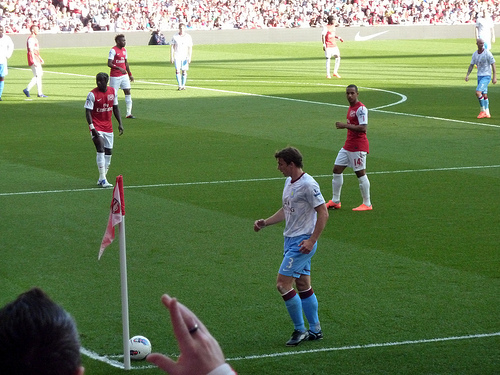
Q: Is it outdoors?
A: Yes, it is outdoors.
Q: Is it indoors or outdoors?
A: It is outdoors.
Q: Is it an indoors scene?
A: No, it is outdoors.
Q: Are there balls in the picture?
A: Yes, there is a ball.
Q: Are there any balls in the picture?
A: Yes, there is a ball.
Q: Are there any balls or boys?
A: Yes, there is a ball.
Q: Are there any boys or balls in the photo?
A: Yes, there is a ball.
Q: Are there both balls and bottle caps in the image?
A: No, there is a ball but no bottle caps.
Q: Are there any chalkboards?
A: No, there are no chalkboards.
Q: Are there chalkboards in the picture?
A: No, there are no chalkboards.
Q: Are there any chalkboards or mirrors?
A: No, there are no chalkboards or mirrors.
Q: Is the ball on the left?
A: Yes, the ball is on the left of the image.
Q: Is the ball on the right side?
A: No, the ball is on the left of the image.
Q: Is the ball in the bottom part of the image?
A: Yes, the ball is in the bottom of the image.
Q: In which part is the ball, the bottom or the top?
A: The ball is in the bottom of the image.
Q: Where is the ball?
A: The ball is on the field.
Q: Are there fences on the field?
A: No, there is a ball on the field.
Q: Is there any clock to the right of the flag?
A: No, there is a ball to the right of the flag.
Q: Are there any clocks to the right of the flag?
A: No, there is a ball to the right of the flag.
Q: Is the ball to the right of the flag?
A: Yes, the ball is to the right of the flag.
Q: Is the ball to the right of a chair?
A: No, the ball is to the right of the flag.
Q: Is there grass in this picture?
A: Yes, there is grass.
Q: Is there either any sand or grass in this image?
A: Yes, there is grass.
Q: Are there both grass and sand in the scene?
A: No, there is grass but no sand.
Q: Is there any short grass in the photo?
A: Yes, there is short grass.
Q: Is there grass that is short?
A: Yes, there is grass that is short.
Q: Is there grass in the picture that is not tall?
A: Yes, there is short grass.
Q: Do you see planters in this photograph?
A: No, there are no planters.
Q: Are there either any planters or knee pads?
A: No, there are no planters or knee pads.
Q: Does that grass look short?
A: Yes, the grass is short.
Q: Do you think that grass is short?
A: Yes, the grass is short.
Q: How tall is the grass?
A: The grass is short.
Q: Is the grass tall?
A: No, the grass is short.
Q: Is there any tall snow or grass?
A: No, there is grass but it is short.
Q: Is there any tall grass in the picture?
A: No, there is grass but it is short.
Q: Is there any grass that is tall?
A: No, there is grass but it is short.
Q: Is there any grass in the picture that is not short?
A: No, there is grass but it is short.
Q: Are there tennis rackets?
A: No, there are no tennis rackets.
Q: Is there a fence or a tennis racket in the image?
A: No, there are no rackets or fences.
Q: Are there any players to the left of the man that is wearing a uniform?
A: Yes, there is a player to the left of the man.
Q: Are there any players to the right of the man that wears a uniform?
A: No, the player is to the left of the man.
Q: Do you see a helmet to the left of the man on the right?
A: No, there is a player to the left of the man.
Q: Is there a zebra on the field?
A: No, there is a player on the field.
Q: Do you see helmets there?
A: No, there are no helmets.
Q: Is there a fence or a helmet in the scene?
A: No, there are no helmets or fences.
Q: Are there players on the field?
A: Yes, there is a player on the field.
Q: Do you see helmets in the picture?
A: No, there are no helmets.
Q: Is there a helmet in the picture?
A: No, there are no helmets.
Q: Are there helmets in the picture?
A: No, there are no helmets.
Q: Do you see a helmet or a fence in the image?
A: No, there are no helmets or fences.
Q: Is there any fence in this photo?
A: No, there are no fences.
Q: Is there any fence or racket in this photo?
A: No, there are no fences or rackets.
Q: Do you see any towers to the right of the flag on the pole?
A: No, there is a player to the right of the flag.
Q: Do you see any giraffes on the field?
A: No, there is a player on the field.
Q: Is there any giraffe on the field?
A: No, there is a player on the field.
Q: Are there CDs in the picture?
A: No, there are no cds.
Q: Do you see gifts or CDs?
A: No, there are no CDs or gifts.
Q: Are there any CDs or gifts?
A: No, there are no CDs or gifts.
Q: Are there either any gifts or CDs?
A: No, there are no CDs or gifts.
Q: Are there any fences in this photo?
A: No, there are no fences.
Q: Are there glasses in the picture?
A: No, there are no glasses.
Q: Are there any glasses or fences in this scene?
A: No, there are no glasses or fences.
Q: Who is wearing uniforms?
A: The men are wearing uniforms.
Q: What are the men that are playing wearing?
A: The men are wearing uniforms.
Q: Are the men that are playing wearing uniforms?
A: Yes, the men are wearing uniforms.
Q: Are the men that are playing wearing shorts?
A: No, the men are wearing uniforms.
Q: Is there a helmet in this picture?
A: No, there are no helmets.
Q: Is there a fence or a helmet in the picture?
A: No, there are no helmets or fences.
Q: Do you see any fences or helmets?
A: No, there are no helmets or fences.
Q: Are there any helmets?
A: No, there are no helmets.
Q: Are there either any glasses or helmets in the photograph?
A: No, there are no helmets or glasses.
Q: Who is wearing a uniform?
A: The man is wearing a uniform.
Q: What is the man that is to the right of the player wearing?
A: The man is wearing a uniform.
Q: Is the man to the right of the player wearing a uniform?
A: Yes, the man is wearing a uniform.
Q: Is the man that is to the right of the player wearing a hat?
A: No, the man is wearing a uniform.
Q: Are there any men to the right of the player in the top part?
A: Yes, there is a man to the right of the player.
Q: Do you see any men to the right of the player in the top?
A: Yes, there is a man to the right of the player.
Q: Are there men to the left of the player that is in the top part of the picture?
A: No, the man is to the right of the player.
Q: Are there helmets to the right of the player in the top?
A: No, there is a man to the right of the player.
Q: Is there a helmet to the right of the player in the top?
A: No, there is a man to the right of the player.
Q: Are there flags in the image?
A: Yes, there is a flag.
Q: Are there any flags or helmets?
A: Yes, there is a flag.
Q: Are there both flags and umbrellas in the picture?
A: No, there is a flag but no umbrellas.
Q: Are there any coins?
A: No, there are no coins.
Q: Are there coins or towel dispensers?
A: No, there are no coins or towel dispensers.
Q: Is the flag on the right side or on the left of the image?
A: The flag is on the left of the image.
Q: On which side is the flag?
A: The flag is on the left of the image.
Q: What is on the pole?
A: The flag is on the pole.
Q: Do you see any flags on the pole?
A: Yes, there is a flag on the pole.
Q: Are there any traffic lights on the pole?
A: No, there is a flag on the pole.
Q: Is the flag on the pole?
A: Yes, the flag is on the pole.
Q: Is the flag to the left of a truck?
A: No, the flag is to the left of a player.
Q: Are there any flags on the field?
A: Yes, there is a flag on the field.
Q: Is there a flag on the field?
A: Yes, there is a flag on the field.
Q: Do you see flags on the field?
A: Yes, there is a flag on the field.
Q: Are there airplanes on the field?
A: No, there is a flag on the field.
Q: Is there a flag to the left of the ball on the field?
A: Yes, there is a flag to the left of the ball.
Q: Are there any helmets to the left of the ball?
A: No, there is a flag to the left of the ball.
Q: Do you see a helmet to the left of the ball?
A: No, there is a flag to the left of the ball.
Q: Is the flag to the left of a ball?
A: Yes, the flag is to the left of a ball.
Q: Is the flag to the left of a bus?
A: No, the flag is to the left of a ball.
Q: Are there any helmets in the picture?
A: No, there are no helmets.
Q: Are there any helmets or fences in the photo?
A: No, there are no helmets or fences.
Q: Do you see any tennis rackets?
A: No, there are no tennis rackets.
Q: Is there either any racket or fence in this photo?
A: No, there are no rackets or fences.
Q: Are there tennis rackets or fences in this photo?
A: No, there are no tennis rackets or fences.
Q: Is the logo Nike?
A: Yes, the logo is nike.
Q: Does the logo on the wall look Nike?
A: Yes, the logo is nike.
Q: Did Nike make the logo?
A: Yes, the logo was made by nike.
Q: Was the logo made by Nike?
A: Yes, the logo was made by nike.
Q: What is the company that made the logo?
A: The company that made the logo is nike.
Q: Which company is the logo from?
A: The logo is from nike.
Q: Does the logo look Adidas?
A: No, the logo is nike.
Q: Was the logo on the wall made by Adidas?
A: No, the logo was made by nike.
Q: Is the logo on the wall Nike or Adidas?
A: The logo is nike.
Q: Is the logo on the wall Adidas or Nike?
A: The logo is nike.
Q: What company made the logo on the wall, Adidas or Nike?
A: The logo was made nike.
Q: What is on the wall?
A: The logo is on the wall.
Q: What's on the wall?
A: The logo is on the wall.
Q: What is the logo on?
A: The logo is on the wall.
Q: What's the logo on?
A: The logo is on the wall.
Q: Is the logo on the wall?
A: Yes, the logo is on the wall.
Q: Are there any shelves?
A: No, there are no shelves.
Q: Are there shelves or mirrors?
A: No, there are no shelves or mirrors.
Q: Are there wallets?
A: No, there are no wallets.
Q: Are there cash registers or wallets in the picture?
A: No, there are no wallets or cash registers.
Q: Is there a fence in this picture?
A: No, there are no fences.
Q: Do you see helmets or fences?
A: No, there are no fences or helmets.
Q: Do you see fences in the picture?
A: No, there are no fences.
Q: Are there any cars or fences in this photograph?
A: No, there are no fences or cars.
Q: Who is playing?
A: The people are playing.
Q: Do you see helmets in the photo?
A: No, there are no helmets.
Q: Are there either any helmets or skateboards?
A: No, there are no helmets or skateboards.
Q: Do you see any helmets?
A: No, there are no helmets.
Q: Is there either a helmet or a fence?
A: No, there are no helmets or fences.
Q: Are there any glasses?
A: No, there are no glasses.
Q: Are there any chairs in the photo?
A: No, there are no chairs.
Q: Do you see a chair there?
A: No, there are no chairs.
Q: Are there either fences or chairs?
A: No, there are no chairs or fences.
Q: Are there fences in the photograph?
A: No, there are no fences.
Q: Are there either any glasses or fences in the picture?
A: No, there are no fences or glasses.